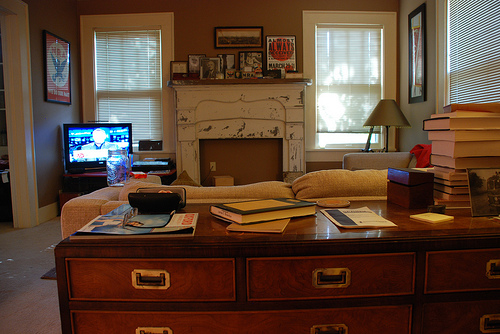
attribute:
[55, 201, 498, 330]
dresser — large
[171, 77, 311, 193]
fireplace — white, white and faded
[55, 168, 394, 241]
couch — white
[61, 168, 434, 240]
couch — white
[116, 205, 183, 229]
glasses — clear and black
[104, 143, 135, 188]
mason jar — clear, glass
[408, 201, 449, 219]
pad — yellow, sticky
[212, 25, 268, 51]
photograph — framed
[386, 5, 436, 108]
painting — framed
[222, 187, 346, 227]
book — yellow, black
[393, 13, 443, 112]
picture — black, framed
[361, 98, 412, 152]
lamp — gray and black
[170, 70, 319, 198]
mantle — white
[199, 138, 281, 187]
fireplace — inoperable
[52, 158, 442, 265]
couch — beige and fabric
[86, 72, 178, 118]
frame — large and white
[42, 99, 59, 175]
frame — thin and black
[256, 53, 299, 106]
frame — thin and black